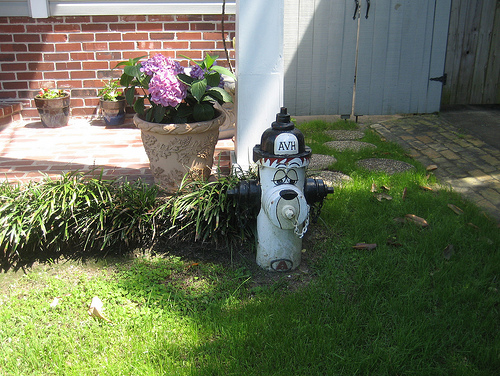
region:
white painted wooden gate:
[283, 0, 450, 115]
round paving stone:
[353, 155, 415, 180]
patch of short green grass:
[1, 117, 499, 374]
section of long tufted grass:
[1, 159, 258, 271]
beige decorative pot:
[131, 104, 226, 194]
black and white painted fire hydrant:
[224, 106, 333, 273]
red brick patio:
[1, 115, 238, 190]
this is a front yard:
[22, 17, 429, 311]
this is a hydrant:
[264, 131, 316, 262]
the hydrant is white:
[247, 121, 341, 325]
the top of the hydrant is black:
[240, 100, 322, 164]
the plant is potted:
[125, 13, 227, 163]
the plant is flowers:
[121, 38, 206, 138]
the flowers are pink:
[145, 64, 202, 128]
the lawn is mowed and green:
[80, 267, 310, 374]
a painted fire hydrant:
[247, 107, 330, 274]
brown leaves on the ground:
[350, 193, 462, 257]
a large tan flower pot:
[129, 112, 234, 192]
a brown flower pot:
[33, 86, 73, 128]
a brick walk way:
[376, 120, 498, 207]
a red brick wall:
[7, 28, 104, 73]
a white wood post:
[224, 3, 291, 177]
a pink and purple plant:
[122, 52, 229, 133]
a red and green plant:
[32, 83, 67, 108]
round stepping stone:
[354, 155, 414, 180]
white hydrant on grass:
[218, 130, 353, 287]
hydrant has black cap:
[265, 120, 310, 158]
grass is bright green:
[362, 254, 420, 334]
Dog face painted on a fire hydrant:
[265, 153, 310, 233]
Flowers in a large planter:
[120, 49, 230, 199]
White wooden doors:
[281, 0, 443, 126]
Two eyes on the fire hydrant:
[271, 169, 299, 188]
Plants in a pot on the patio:
[33, 86, 70, 128]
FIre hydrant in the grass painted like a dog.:
[248, 103, 329, 273]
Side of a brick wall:
[0, 10, 228, 112]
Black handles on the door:
[348, 0, 371, 21]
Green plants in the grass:
[0, 170, 257, 266]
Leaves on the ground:
[342, 171, 457, 259]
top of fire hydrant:
[249, 103, 315, 165]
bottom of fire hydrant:
[256, 165, 318, 267]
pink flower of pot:
[141, 66, 183, 113]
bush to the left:
[0, 165, 161, 267]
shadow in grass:
[155, 186, 494, 367]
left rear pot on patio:
[32, 65, 79, 131]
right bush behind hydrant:
[146, 159, 270, 262]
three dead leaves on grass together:
[360, 171, 395, 205]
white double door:
[277, 3, 460, 117]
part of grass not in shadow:
[0, 258, 172, 366]